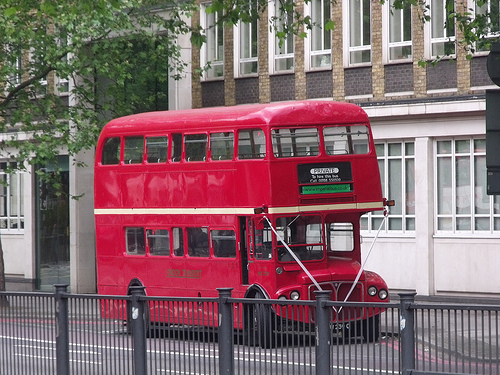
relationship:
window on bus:
[270, 127, 319, 156] [92, 102, 391, 344]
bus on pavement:
[81, 97, 326, 373] [1, 265, 498, 356]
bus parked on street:
[92, 102, 391, 344] [4, 297, 412, 369]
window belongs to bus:
[234, 126, 270, 155] [92, 102, 391, 344]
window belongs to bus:
[123, 221, 143, 251] [84, 87, 392, 330]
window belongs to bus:
[125, 227, 146, 255] [92, 102, 391, 344]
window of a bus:
[275, 213, 322, 260] [92, 102, 391, 344]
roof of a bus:
[98, 95, 368, 137] [92, 102, 391, 344]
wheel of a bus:
[116, 282, 159, 334] [92, 102, 391, 344]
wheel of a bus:
[242, 288, 285, 341] [92, 102, 391, 344]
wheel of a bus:
[363, 317, 393, 349] [92, 102, 391, 344]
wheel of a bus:
[251, 304, 275, 348] [92, 102, 391, 344]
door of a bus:
[232, 209, 273, 312] [92, 102, 391, 344]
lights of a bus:
[270, 282, 392, 310] [92, 102, 391, 344]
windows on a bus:
[129, 225, 231, 262] [92, 102, 391, 344]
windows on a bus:
[211, 229, 235, 259] [92, 102, 391, 344]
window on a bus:
[234, 126, 270, 155] [92, 102, 391, 344]